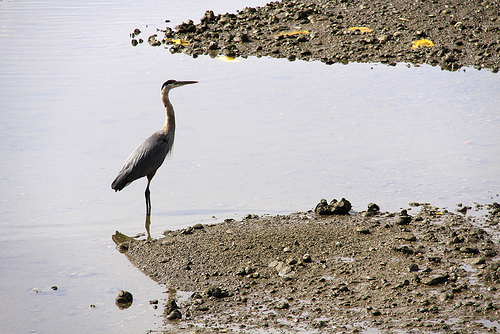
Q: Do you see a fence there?
A: No, there are no fences.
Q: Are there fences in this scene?
A: No, there are no fences.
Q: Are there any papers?
A: No, there are no papers.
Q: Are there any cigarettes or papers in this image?
A: No, there are no papers or cigarettes.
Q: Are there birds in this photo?
A: Yes, there is a bird.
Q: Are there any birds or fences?
A: Yes, there is a bird.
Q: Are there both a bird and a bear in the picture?
A: No, there is a bird but no bears.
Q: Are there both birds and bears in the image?
A: No, there is a bird but no bears.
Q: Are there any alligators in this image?
A: No, there are no alligators.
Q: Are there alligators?
A: No, there are no alligators.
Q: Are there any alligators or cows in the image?
A: No, there are no alligators or cows.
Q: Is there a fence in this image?
A: No, there are no fences.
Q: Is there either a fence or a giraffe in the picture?
A: No, there are no fences or giraffes.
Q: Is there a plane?
A: No, there are no airplanes.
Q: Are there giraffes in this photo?
A: No, there are no giraffes.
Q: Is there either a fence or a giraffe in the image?
A: No, there are no giraffes or fences.